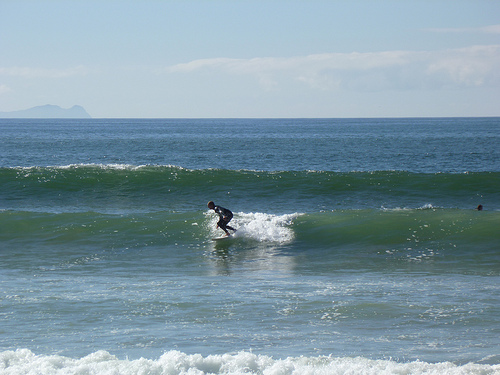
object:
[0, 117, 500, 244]
water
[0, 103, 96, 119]
mountain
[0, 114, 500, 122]
horizon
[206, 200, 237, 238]
surfer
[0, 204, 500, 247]
wave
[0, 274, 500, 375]
water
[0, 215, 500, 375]
beach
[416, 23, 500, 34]
clouds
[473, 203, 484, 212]
person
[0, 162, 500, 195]
waves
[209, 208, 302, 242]
water splashes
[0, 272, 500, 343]
crystal/clear water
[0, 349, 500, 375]
incoming waves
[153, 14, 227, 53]
part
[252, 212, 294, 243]
part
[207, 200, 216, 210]
swimmer head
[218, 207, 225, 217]
part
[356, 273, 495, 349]
part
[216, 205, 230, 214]
back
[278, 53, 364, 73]
part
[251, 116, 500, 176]
part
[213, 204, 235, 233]
black wetsuit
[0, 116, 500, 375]
ocean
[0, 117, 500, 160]
calm ripples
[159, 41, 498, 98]
cloud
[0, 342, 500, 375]
wave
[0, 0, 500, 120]
sky